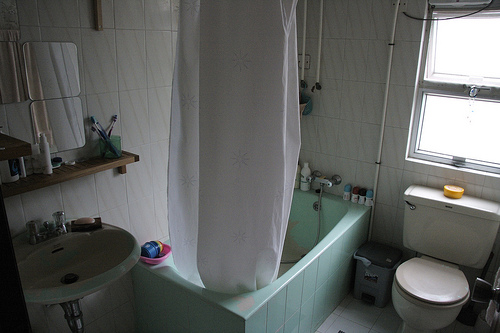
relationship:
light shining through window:
[438, 107, 492, 144] [368, 10, 495, 192]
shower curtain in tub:
[163, 5, 307, 297] [137, 185, 382, 331]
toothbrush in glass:
[110, 115, 123, 137] [98, 135, 126, 161]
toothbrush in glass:
[84, 115, 99, 136] [98, 135, 126, 161]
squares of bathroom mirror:
[1, 41, 26, 105] [0, 37, 90, 190]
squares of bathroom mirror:
[20, 38, 80, 101] [0, 37, 90, 190]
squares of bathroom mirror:
[0, 96, 35, 150] [0, 37, 90, 190]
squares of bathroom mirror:
[26, 95, 87, 152] [0, 37, 90, 190]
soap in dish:
[72, 216, 97, 226] [67, 218, 104, 233]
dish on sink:
[67, 218, 104, 233] [5, 207, 142, 311]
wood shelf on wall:
[0, 140, 142, 202] [8, 0, 177, 235]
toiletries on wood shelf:
[1, 152, 20, 182] [0, 148, 142, 201]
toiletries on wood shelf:
[16, 153, 26, 176] [0, 148, 142, 201]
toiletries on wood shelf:
[29, 145, 44, 175] [0, 148, 142, 201]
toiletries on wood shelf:
[37, 131, 55, 174] [0, 148, 142, 201]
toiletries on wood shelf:
[50, 154, 65, 172] [0, 148, 142, 201]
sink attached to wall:
[5, 217, 145, 309] [21, 214, 142, 325]